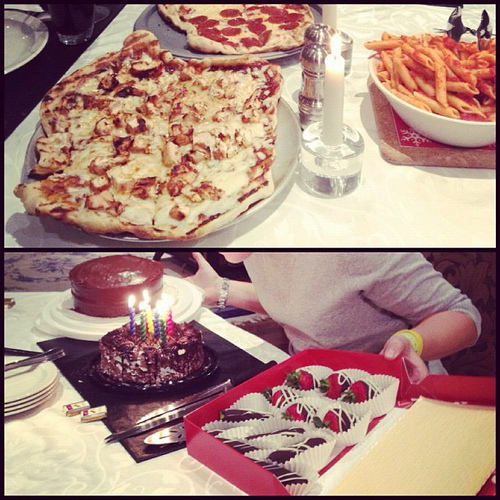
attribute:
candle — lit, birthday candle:
[123, 291, 138, 335]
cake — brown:
[91, 328, 223, 385]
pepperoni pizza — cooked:
[157, 9, 314, 53]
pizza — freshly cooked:
[11, 25, 285, 242]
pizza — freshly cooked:
[155, 1, 317, 56]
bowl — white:
[333, 43, 490, 168]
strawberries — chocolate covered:
[348, 380, 383, 405]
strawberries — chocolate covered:
[321, 400, 351, 432]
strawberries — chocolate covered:
[321, 362, 352, 393]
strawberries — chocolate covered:
[289, 360, 313, 385]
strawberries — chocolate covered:
[268, 383, 296, 405]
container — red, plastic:
[178, 343, 490, 495]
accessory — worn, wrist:
[218, 274, 226, 308]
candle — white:
[321, 53, 346, 150]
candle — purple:
[118, 296, 140, 341]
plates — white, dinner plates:
[2, 349, 61, 419]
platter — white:
[36, 275, 204, 340]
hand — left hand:
[377, 321, 431, 386]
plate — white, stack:
[0, 349, 62, 402]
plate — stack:
[1, 374, 63, 413]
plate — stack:
[0, 399, 56, 423]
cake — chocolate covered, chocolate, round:
[66, 253, 165, 318]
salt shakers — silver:
[296, 24, 324, 133]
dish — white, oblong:
[369, 56, 496, 161]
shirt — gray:
[245, 255, 466, 372]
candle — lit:
[121, 288, 138, 336]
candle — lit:
[160, 290, 179, 342]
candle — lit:
[133, 297, 148, 341]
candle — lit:
[140, 289, 159, 335]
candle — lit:
[151, 297, 166, 333]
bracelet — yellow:
[401, 333, 418, 349]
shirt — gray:
[242, 252, 482, 375]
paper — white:
[275, 437, 336, 462]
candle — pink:
[166, 306, 176, 335]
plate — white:
[25, 95, 302, 239]